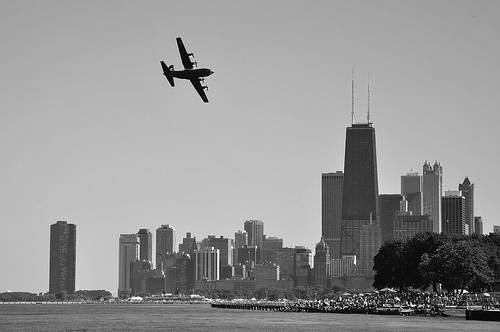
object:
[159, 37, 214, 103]
plane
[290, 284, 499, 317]
people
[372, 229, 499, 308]
trees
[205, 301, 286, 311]
pier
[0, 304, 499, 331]
water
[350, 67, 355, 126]
antennas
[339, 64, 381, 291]
skyscraper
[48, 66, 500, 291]
buildings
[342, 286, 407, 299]
umbrellas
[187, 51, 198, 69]
propellers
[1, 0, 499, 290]
sky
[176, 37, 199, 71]
wings